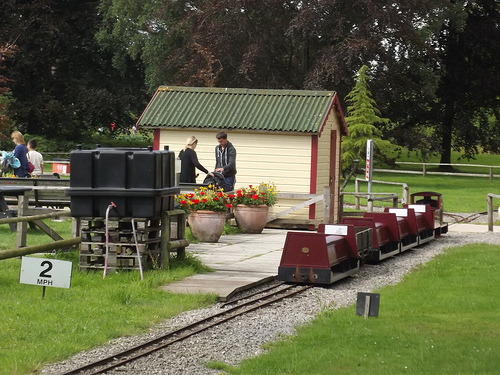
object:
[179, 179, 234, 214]
flowers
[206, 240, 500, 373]
grass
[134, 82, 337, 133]
green roof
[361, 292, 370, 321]
handle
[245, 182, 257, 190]
red flower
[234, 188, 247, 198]
red flower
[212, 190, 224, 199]
red flower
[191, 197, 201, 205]
red flower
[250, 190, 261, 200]
red flower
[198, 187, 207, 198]
red flower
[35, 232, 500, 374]
gravel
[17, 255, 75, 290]
board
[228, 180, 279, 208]
flowers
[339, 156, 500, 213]
fence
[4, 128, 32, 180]
person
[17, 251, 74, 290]
sign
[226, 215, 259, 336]
grass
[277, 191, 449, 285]
train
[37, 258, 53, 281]
number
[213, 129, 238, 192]
people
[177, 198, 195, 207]
red flower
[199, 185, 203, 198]
red flower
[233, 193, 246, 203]
red flower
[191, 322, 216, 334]
tracks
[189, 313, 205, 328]
tracks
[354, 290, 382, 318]
object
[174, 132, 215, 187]
person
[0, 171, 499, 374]
ground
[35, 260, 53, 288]
display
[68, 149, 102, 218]
box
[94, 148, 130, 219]
box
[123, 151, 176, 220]
box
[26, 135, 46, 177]
person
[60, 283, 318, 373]
track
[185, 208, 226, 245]
item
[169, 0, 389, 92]
tree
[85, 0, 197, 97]
tree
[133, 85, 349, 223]
building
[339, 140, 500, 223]
yard